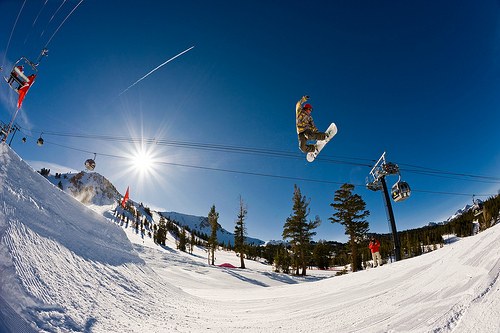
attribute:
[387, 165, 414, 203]
gondola — ski lift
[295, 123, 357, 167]
snowboard — white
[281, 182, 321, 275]
tree — green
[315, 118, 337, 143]
snowboard — white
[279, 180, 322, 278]
tree — pine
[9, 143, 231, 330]
ramp — large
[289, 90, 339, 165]
skateboarder — high-flyer